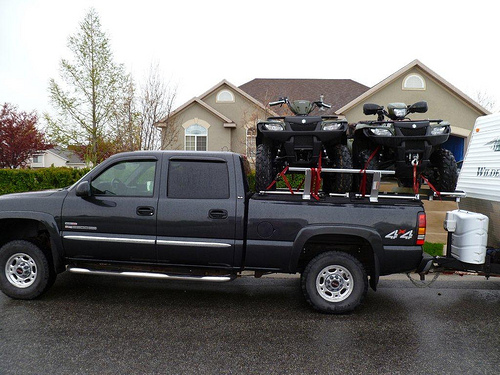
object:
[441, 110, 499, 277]
rv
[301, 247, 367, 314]
tire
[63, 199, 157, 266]
door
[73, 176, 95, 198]
mirror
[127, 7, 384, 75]
sky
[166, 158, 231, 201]
window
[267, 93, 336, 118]
handlebars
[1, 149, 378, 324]
four wheeler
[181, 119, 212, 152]
window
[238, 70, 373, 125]
roof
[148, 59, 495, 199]
house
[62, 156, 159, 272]
black door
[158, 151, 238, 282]
black door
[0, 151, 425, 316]
truck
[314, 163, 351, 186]
straps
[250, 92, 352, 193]
four wheelers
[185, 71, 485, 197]
walls